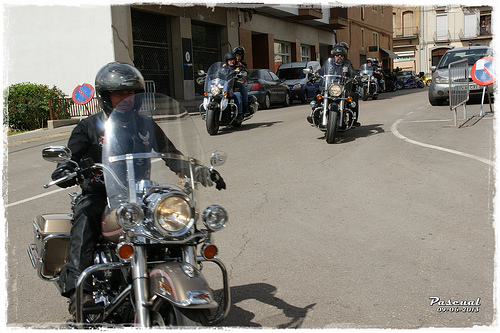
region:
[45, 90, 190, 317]
a cop on a bike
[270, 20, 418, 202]
a cop on a bike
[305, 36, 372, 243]
a cop on a bike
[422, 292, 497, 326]
date stamp on bottom right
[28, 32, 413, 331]
people on motorcycles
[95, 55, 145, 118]
reflections on man's helmet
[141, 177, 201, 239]
headlight of motorcycle is turned on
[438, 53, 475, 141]
metal railing on two posts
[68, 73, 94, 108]
blue and red circular sign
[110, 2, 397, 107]
buildings situated very close together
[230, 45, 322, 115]
two vehicles parked facing each other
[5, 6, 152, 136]
green shrubbery beside building's white wall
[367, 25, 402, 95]
small awning over entrance to building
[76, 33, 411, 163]
four motorcyclists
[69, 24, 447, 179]
all of the people are wearing helmets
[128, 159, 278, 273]
the lights on the bikes are on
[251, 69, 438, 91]
cars are parked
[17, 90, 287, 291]
a man rides solo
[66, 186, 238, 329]
the motorcycle is copper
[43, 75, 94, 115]
a blue and red sign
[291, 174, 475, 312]
the street is light grey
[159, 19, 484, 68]
buildings in the background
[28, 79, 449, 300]
the sun is out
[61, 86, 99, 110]
Red and blue sign.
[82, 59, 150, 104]
Motorcycle rider is wearing a helmet.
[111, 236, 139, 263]
Red light on the motorcycle.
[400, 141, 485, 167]
Solid white line on the road.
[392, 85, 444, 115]
Small white lines on the road.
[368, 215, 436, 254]
The road is brownish grey.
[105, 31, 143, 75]
Crack in the wall.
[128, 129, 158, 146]
Logo on the biker's jacket.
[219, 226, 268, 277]
Crack in the road.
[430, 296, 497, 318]
Name and date on the bottom right corner.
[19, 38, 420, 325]
motorcyclists in the street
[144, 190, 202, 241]
front light of a motorcycle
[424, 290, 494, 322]
photographer copyright in bottom corner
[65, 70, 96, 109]
traffic sign on the sidewalk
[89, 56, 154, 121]
helmet on motorcyclist's head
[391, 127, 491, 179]
white painted line in street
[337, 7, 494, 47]
buildings in the background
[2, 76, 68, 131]
green bush by a building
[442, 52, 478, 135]
metal barricade fence in road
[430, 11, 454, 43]
window of a building